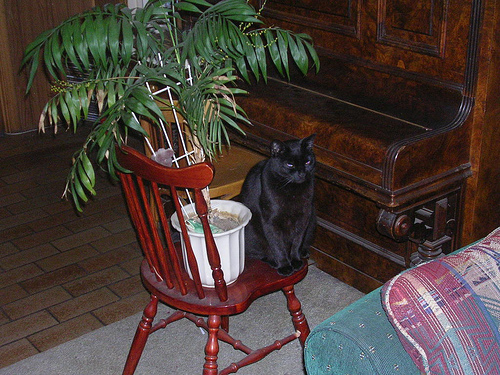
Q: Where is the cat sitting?
A: On the chair.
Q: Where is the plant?
A: On the chair.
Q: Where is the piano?
A: Next to the cat.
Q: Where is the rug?
A: On the floor.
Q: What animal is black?
A: The cat.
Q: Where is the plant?
A: On the chair.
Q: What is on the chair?
A: The plant.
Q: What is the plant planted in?
A: A white pot.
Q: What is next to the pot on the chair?
A: The black cat.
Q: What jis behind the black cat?
A: The brown piano.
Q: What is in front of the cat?
A: A couch.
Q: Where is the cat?
A: The cat is sitting on the chair.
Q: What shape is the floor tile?
A: The shape of a brick.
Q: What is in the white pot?
A: A green plant.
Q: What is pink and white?
A: The pillow.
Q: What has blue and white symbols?
A: The couch.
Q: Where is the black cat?
A: On the chair.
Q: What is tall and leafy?
A: The plant.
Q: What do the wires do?
A: Hold the plant.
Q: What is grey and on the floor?
A: Carpet.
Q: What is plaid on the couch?
A: A pillow.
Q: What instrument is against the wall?
A: A piano.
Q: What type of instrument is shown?
A: A piano.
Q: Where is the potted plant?
A: On the chair.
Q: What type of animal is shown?
A: A cat.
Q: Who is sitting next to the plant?
A: The cat.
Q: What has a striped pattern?
A: The pillow.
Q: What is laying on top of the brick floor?
A: A carpet.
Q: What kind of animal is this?
A: A cat.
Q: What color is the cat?
A: Black.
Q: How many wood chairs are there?
A: Two.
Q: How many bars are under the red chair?
A: Three.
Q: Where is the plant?
A: On the red chair.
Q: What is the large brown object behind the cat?
A: A piano.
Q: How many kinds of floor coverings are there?
A: Two.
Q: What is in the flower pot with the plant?
A: A trellis.